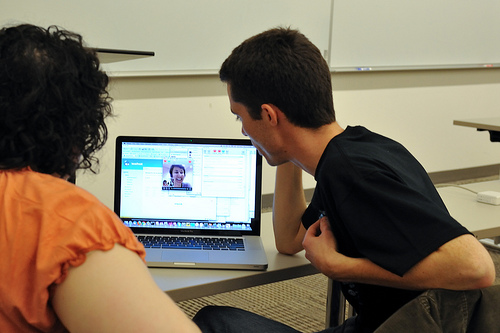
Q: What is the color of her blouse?
A: Orange.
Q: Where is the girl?
A: Next to the boy.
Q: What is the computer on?
A: The table.